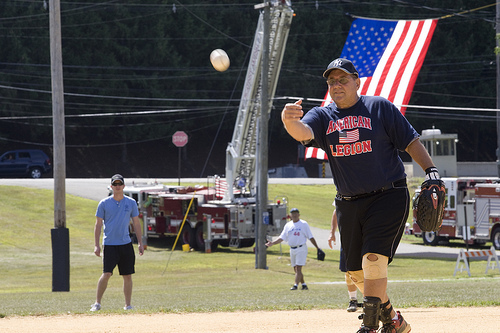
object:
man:
[280, 58, 449, 333]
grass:
[0, 180, 499, 318]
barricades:
[453, 251, 500, 279]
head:
[327, 61, 360, 102]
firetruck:
[107, 0, 300, 255]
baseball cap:
[322, 58, 359, 79]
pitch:
[0, 0, 500, 180]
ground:
[185, 261, 249, 300]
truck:
[411, 176, 500, 252]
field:
[0, 178, 500, 333]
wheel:
[490, 224, 500, 252]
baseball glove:
[316, 249, 325, 261]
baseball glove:
[413, 178, 449, 232]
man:
[90, 175, 145, 315]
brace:
[362, 253, 389, 280]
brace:
[352, 269, 366, 295]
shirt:
[95, 194, 139, 246]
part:
[341, 19, 399, 77]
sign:
[172, 131, 188, 147]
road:
[0, 172, 339, 190]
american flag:
[302, 17, 437, 164]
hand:
[281, 99, 303, 122]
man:
[264, 208, 326, 290]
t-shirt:
[278, 219, 314, 248]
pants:
[291, 245, 310, 267]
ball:
[209, 47, 229, 71]